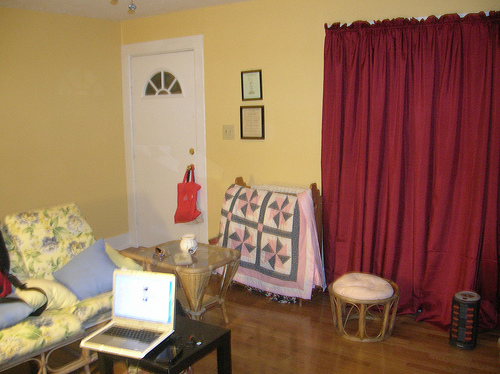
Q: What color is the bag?
A: Pink.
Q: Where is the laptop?
A: On the table.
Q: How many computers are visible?
A: 1.